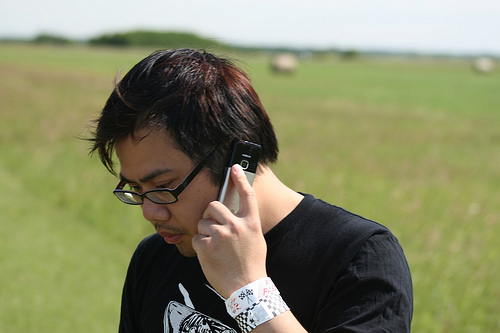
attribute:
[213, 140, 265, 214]
cellphone — gray, black, silver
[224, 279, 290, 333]
bracelet — checkered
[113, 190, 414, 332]
shirt — black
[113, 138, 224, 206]
glasses — black, plastic, oblong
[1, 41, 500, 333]
field — blurry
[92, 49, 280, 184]
hair — brown, dark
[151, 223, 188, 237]
moustache — black